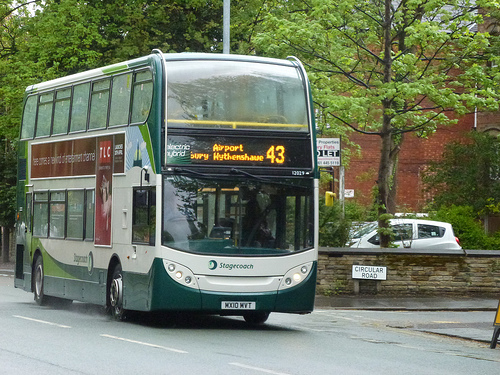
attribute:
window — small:
[129, 69, 152, 125]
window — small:
[107, 72, 133, 128]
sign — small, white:
[348, 262, 393, 288]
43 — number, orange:
[257, 141, 292, 171]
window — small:
[33, 88, 53, 138]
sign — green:
[308, 138, 345, 170]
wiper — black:
[165, 157, 238, 182]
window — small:
[52, 86, 70, 136]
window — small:
[69, 81, 89, 133]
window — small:
[88, 79, 108, 131]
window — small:
[111, 72, 131, 127]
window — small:
[89, 84, 109, 129]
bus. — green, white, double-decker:
[17, 32, 389, 329]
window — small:
[114, 75, 168, 119]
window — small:
[64, 188, 83, 235]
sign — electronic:
[166, 132, 311, 170]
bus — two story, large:
[12, 49, 318, 320]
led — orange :
[181, 139, 290, 166]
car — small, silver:
[338, 213, 463, 255]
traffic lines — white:
[10, 308, 290, 373]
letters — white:
[320, 147, 339, 157]